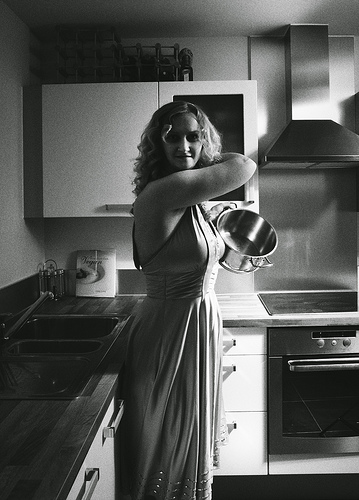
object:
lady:
[122, 97, 257, 500]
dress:
[118, 203, 227, 500]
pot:
[213, 200, 280, 275]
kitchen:
[0, 0, 359, 500]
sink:
[0, 310, 133, 401]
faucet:
[0, 289, 54, 342]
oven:
[266, 323, 359, 456]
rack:
[28, 24, 181, 82]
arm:
[133, 150, 257, 210]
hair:
[129, 98, 223, 215]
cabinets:
[156, 76, 262, 221]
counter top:
[0, 268, 358, 499]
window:
[281, 353, 359, 440]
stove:
[256, 290, 357, 315]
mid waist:
[144, 268, 218, 305]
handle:
[105, 203, 132, 211]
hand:
[208, 201, 238, 222]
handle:
[248, 176, 254, 204]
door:
[281, 351, 359, 439]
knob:
[316, 339, 325, 349]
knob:
[342, 338, 351, 348]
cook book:
[75, 247, 120, 298]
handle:
[102, 396, 127, 441]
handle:
[75, 466, 102, 499]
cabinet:
[65, 385, 127, 500]